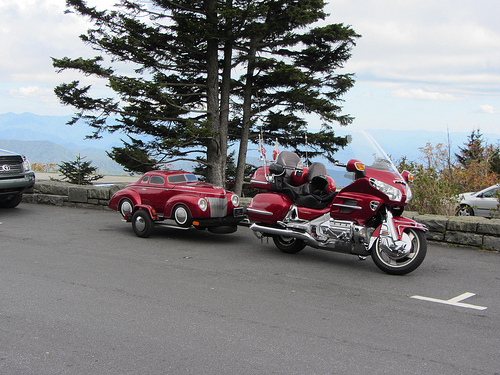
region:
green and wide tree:
[94, 16, 336, 176]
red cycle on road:
[261, 139, 444, 291]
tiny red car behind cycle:
[106, 171, 243, 238]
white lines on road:
[423, 273, 489, 340]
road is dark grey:
[133, 221, 363, 354]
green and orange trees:
[401, 143, 486, 223]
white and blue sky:
[374, 1, 459, 136]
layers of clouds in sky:
[364, 13, 484, 149]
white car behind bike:
[441, 176, 495, 218]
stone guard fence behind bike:
[429, 208, 497, 256]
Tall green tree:
[133, 2, 354, 150]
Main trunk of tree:
[204, 35, 226, 184]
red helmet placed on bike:
[308, 175, 337, 193]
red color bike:
[249, 150, 435, 277]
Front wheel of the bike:
[371, 222, 427, 274]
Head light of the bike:
[371, 183, 413, 203]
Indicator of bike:
[353, 161, 367, 171]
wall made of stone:
[429, 216, 498, 248]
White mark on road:
[411, 291, 488, 315]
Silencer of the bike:
[251, 223, 314, 238]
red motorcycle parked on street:
[245, 148, 418, 278]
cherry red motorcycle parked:
[245, 126, 430, 268]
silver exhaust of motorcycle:
[252, 223, 292, 235]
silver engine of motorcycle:
[312, 217, 360, 242]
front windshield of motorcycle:
[352, 125, 387, 169]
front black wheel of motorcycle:
[370, 227, 422, 261]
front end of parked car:
[0, 148, 34, 202]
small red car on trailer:
[106, 163, 237, 238]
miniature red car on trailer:
[100, 167, 239, 233]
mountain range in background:
[35, 101, 87, 169]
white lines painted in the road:
[410, 276, 493, 334]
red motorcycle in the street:
[234, 123, 425, 286]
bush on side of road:
[51, 157, 100, 194]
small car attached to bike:
[109, 149, 236, 249]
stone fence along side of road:
[428, 205, 491, 257]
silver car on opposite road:
[446, 173, 494, 214]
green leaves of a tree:
[104, 7, 187, 147]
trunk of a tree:
[198, 38, 235, 184]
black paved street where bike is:
[11, 231, 238, 356]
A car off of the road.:
[442, 172, 497, 218]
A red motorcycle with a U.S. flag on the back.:
[246, 131, 431, 292]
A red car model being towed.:
[108, 155, 245, 238]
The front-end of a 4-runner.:
[0, 144, 35, 225]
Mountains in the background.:
[8, 104, 130, 179]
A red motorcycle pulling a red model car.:
[105, 136, 435, 283]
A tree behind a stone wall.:
[35, 151, 107, 221]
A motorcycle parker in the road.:
[248, 135, 430, 280]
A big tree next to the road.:
[46, 0, 365, 197]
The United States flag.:
[253, 138, 278, 170]